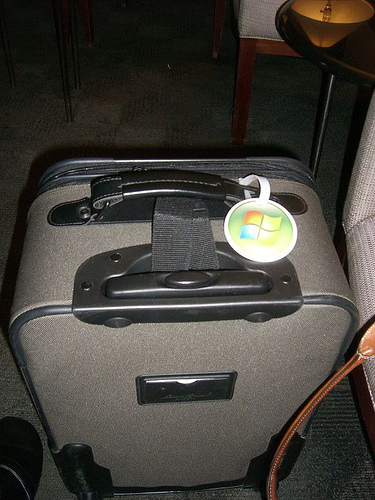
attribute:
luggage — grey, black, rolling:
[6, 139, 359, 499]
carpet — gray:
[8, 38, 226, 142]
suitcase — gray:
[0, 125, 373, 499]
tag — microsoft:
[227, 189, 296, 264]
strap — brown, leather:
[270, 359, 345, 483]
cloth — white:
[344, 228, 363, 257]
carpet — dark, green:
[96, 112, 148, 135]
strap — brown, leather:
[262, 361, 350, 452]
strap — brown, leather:
[271, 369, 353, 461]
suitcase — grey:
[20, 148, 343, 475]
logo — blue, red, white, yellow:
[238, 208, 282, 246]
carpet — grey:
[0, 0, 374, 499]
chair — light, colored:
[334, 85, 374, 461]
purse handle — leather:
[265, 319, 374, 499]